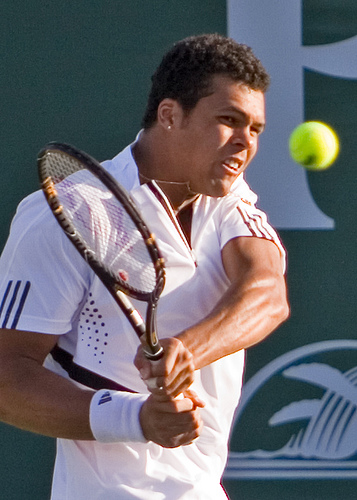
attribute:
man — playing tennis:
[0, 34, 292, 499]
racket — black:
[34, 140, 167, 389]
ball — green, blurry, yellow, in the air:
[288, 120, 341, 171]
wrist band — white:
[90, 388, 148, 446]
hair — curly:
[141, 33, 269, 131]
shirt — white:
[3, 128, 285, 499]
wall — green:
[1, 1, 355, 498]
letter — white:
[224, 0, 356, 234]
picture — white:
[227, 338, 356, 482]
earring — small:
[166, 125, 173, 132]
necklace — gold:
[140, 169, 198, 198]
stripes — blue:
[1, 280, 31, 330]